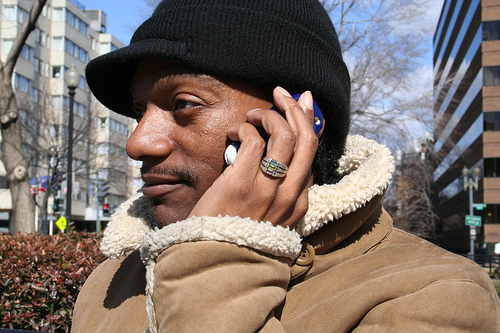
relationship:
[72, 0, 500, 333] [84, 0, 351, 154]
man wearing cap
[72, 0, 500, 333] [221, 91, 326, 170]
man holding phone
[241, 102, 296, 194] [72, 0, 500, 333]
finger on man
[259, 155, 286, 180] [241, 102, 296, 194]
ring on finger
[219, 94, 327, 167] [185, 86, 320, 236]
cell phone in hand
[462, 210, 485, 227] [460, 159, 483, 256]
sign on pole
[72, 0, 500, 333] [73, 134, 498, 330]
man wearing coat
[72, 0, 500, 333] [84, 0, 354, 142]
man wearing cap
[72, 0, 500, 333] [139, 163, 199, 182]
man has mustache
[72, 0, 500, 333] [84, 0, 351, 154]
man wears cap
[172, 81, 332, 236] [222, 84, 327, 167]
hand holds cell phone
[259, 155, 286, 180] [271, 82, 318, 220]
ring on finger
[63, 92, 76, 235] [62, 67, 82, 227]
pole with streetlamp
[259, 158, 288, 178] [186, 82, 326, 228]
ring on hand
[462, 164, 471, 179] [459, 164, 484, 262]
light on pole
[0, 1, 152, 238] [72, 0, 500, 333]
building to man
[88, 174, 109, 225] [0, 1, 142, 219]
lights in front building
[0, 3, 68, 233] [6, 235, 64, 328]
tree behind bush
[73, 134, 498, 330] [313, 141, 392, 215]
coat has wool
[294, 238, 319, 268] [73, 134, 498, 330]
button in a coat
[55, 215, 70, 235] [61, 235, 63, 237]
sign in a pole